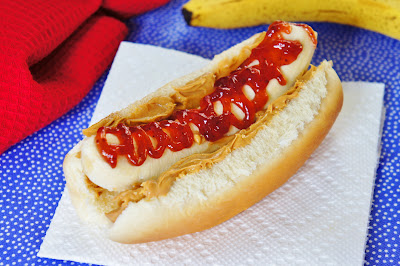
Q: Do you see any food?
A: Yes, there is food.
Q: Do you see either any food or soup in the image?
A: Yes, there is food.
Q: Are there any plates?
A: No, there are no plates.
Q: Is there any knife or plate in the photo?
A: No, there are no plates or knives.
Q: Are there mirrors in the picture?
A: No, there are no mirrors.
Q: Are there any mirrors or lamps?
A: No, there are no mirrors or lamps.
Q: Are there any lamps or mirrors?
A: No, there are no mirrors or lamps.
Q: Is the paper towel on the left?
A: Yes, the paper towel is on the left of the image.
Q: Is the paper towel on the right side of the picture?
A: No, the paper towel is on the left of the image.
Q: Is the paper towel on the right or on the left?
A: The paper towel is on the left of the image.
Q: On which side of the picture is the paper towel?
A: The paper towel is on the left of the image.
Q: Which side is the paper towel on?
A: The paper towel is on the left of the image.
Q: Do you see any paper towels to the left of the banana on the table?
A: Yes, there is a paper towel to the left of the banana.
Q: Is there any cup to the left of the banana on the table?
A: No, there is a paper towel to the left of the banana.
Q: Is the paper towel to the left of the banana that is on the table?
A: Yes, the paper towel is to the left of the banana.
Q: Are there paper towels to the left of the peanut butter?
A: Yes, there is a paper towel to the left of the peanut butter.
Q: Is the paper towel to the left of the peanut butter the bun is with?
A: Yes, the paper towel is to the left of the peanut butter.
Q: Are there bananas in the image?
A: Yes, there is a banana.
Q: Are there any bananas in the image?
A: Yes, there is a banana.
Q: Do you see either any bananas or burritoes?
A: Yes, there is a banana.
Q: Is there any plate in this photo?
A: No, there are no plates.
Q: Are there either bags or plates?
A: No, there are no plates or bags.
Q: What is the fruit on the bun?
A: The fruit is a banana.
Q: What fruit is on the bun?
A: The fruit is a banana.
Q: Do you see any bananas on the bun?
A: Yes, there is a banana on the bun.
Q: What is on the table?
A: The banana is on the table.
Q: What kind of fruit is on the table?
A: The fruit is a banana.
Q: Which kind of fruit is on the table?
A: The fruit is a banana.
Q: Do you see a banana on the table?
A: Yes, there is a banana on the table.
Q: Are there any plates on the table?
A: No, there is a banana on the table.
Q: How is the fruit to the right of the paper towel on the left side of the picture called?
A: The fruit is a banana.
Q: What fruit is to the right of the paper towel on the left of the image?
A: The fruit is a banana.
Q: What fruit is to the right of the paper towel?
A: The fruit is a banana.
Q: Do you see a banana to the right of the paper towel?
A: Yes, there is a banana to the right of the paper towel.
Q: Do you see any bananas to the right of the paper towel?
A: Yes, there is a banana to the right of the paper towel.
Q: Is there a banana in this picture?
A: Yes, there is a banana.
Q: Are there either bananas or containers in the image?
A: Yes, there is a banana.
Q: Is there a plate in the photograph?
A: No, there are no plates.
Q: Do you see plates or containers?
A: No, there are no plates or containers.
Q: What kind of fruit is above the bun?
A: The fruit is a banana.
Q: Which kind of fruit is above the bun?
A: The fruit is a banana.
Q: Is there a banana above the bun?
A: Yes, there is a banana above the bun.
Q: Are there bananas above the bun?
A: Yes, there is a banana above the bun.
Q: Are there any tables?
A: Yes, there is a table.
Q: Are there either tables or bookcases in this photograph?
A: Yes, there is a table.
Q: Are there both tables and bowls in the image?
A: No, there is a table but no bowls.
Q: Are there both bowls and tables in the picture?
A: No, there is a table but no bowls.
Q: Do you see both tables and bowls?
A: No, there is a table but no bowls.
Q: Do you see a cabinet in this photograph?
A: No, there are no cabinets.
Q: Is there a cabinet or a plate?
A: No, there are no cabinets or plates.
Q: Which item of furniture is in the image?
A: The piece of furniture is a table.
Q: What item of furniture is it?
A: The piece of furniture is a table.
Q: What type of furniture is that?
A: This is a table.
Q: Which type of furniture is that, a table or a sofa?
A: This is a table.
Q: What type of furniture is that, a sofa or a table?
A: This is a table.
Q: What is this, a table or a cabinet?
A: This is a table.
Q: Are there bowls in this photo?
A: No, there are no bowls.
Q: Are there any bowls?
A: No, there are no bowls.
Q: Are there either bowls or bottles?
A: No, there are no bowls or bottles.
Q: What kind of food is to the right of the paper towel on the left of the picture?
A: The food is peanut butter.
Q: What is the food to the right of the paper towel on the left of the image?
A: The food is peanut butter.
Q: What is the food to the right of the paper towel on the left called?
A: The food is peanut butter.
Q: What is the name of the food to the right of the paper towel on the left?
A: The food is peanut butter.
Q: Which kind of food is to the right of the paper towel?
A: The food is peanut butter.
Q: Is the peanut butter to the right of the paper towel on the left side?
A: Yes, the peanut butter is to the right of the paper towel.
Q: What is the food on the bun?
A: The food is peanut butter.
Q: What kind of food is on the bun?
A: The food is peanut butter.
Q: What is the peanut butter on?
A: The peanut butter is on the bun.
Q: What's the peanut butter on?
A: The peanut butter is on the bun.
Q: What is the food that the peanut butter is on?
A: The food is a bun.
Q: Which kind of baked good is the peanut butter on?
A: The peanut butter is on the bun.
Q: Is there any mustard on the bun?
A: No, there is peanut butter on the bun.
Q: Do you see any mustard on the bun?
A: No, there is peanut butter on the bun.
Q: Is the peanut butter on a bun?
A: Yes, the peanut butter is on a bun.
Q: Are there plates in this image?
A: No, there are no plates.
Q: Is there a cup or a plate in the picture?
A: No, there are no plates or cups.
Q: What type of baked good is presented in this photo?
A: The baked good is a bun.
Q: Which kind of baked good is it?
A: The food is a bun.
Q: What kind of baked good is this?
A: This is a bun.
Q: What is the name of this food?
A: This is a bun.